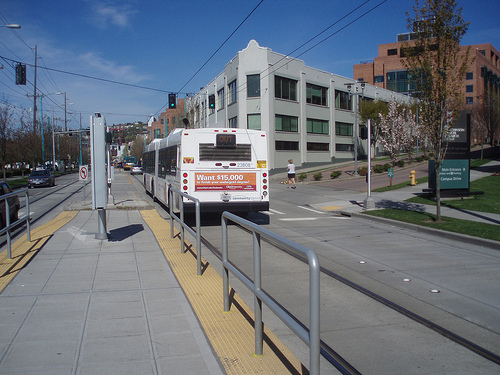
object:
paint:
[139, 206, 311, 375]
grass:
[368, 157, 500, 242]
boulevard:
[0, 159, 498, 375]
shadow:
[0, 232, 52, 281]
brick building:
[353, 23, 500, 162]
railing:
[0, 186, 33, 263]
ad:
[194, 172, 255, 192]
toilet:
[209, 92, 216, 110]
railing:
[218, 210, 321, 375]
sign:
[425, 110, 473, 194]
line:
[278, 216, 353, 222]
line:
[296, 205, 324, 214]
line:
[269, 209, 285, 215]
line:
[258, 210, 274, 215]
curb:
[141, 209, 318, 375]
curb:
[0, 211, 77, 292]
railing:
[169, 186, 202, 277]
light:
[211, 104, 214, 107]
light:
[171, 104, 175, 106]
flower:
[374, 102, 421, 165]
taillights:
[263, 172, 268, 197]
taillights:
[183, 172, 188, 201]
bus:
[122, 155, 139, 170]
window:
[245, 73, 263, 96]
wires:
[0, 0, 393, 113]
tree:
[396, 0, 479, 223]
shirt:
[287, 163, 295, 173]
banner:
[194, 171, 258, 192]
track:
[0, 242, 500, 375]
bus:
[137, 127, 269, 224]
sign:
[79, 164, 88, 181]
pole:
[82, 181, 86, 206]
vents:
[198, 143, 254, 162]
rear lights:
[181, 191, 189, 199]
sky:
[0, 0, 500, 129]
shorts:
[287, 172, 296, 178]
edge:
[136, 205, 314, 375]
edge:
[0, 207, 81, 294]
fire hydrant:
[409, 170, 418, 185]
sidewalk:
[281, 150, 498, 198]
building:
[54, 36, 442, 171]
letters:
[439, 166, 466, 181]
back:
[181, 127, 270, 213]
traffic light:
[208, 93, 216, 109]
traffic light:
[167, 92, 178, 109]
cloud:
[0, 0, 500, 123]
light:
[183, 173, 188, 178]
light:
[183, 179, 188, 185]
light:
[263, 173, 269, 178]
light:
[263, 178, 268, 184]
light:
[262, 185, 268, 189]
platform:
[0, 169, 314, 375]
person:
[287, 159, 296, 190]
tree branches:
[376, 95, 425, 165]